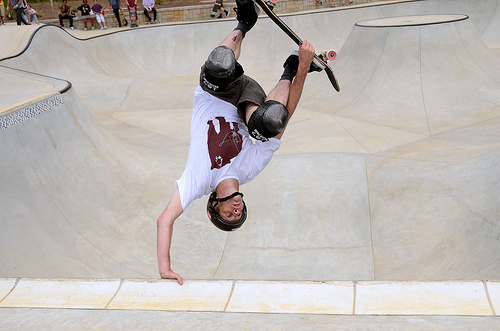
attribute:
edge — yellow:
[115, 309, 353, 314]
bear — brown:
[211, 129, 243, 157]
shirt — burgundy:
[193, 104, 268, 184]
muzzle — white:
[233, 132, 237, 136]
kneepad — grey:
[214, 52, 231, 73]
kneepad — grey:
[273, 108, 285, 125]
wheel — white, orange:
[324, 52, 343, 60]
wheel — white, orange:
[271, 0, 277, 4]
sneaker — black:
[241, 3, 251, 20]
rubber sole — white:
[257, 9, 259, 12]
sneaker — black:
[289, 58, 297, 68]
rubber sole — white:
[294, 50, 295, 53]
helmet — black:
[211, 215, 225, 225]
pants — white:
[96, 16, 105, 20]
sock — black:
[284, 69, 292, 74]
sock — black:
[236, 22, 246, 30]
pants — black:
[236, 84, 253, 94]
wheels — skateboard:
[321, 47, 337, 62]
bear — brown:
[206, 115, 243, 168]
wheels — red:
[321, 45, 344, 65]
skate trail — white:
[5, 1, 499, 311]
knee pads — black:
[201, 46, 298, 148]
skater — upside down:
[112, 51, 324, 252]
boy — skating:
[155, 2, 315, 282]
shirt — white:
[175, 82, 282, 209]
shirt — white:
[172, 90, 294, 210]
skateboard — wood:
[253, 4, 343, 96]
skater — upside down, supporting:
[156, 0, 326, 287]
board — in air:
[231, 0, 356, 104]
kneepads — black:
[261, 104, 290, 137]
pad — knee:
[195, 38, 235, 104]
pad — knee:
[251, 98, 291, 151]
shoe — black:
[226, 3, 263, 34]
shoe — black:
[272, 46, 323, 73]